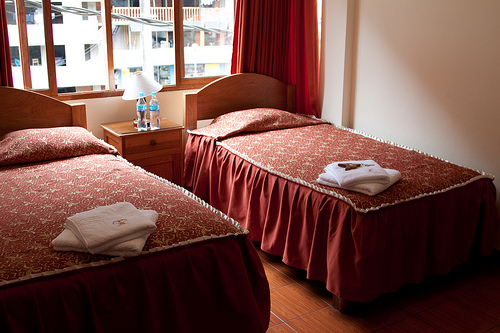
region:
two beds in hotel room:
[3, 11, 489, 316]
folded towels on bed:
[309, 152, 407, 204]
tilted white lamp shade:
[118, 67, 163, 108]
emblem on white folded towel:
[111, 215, 131, 230]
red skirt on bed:
[246, 197, 339, 267]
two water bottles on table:
[133, 88, 168, 135]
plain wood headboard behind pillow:
[176, 67, 307, 122]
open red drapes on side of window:
[231, 10, 317, 80]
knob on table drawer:
[142, 136, 167, 152]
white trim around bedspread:
[403, 188, 447, 204]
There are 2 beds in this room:
[183, 67, 499, 312]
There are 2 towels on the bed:
[50, 195, 161, 260]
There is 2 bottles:
[135, 88, 164, 135]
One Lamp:
[119, 64, 162, 127]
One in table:
[99, 119, 194, 193]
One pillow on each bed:
[191, 101, 318, 143]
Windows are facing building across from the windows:
[50, 43, 73, 73]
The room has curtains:
[226, 0, 326, 118]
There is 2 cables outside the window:
[24, 0, 231, 35]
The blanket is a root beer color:
[186, 107, 496, 303]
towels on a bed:
[310, 150, 408, 205]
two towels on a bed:
[42, 196, 172, 257]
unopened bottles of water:
[132, 82, 169, 137]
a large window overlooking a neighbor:
[0, 1, 238, 99]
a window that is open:
[0, 0, 58, 105]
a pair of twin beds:
[0, 72, 497, 332]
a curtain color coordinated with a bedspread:
[225, 4, 357, 157]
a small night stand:
[100, 111, 187, 191]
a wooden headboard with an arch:
[179, 68, 305, 133]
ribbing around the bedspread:
[192, 112, 491, 223]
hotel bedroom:
[17, 12, 454, 319]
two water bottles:
[125, 91, 175, 136]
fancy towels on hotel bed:
[297, 132, 414, 229]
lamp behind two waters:
[112, 60, 184, 145]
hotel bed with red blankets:
[171, 48, 480, 308]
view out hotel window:
[28, 12, 243, 87]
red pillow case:
[207, 70, 327, 160]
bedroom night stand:
[100, 112, 213, 211]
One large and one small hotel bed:
[0, 54, 495, 322]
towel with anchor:
[42, 188, 171, 290]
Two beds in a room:
[6, 63, 498, 332]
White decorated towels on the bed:
[298, 143, 418, 208]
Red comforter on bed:
[175, 98, 497, 321]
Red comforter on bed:
[0, 113, 282, 328]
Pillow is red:
[176, 101, 336, 144]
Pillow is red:
[0, 117, 141, 163]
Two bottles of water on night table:
[126, 86, 164, 136]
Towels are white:
[37, 194, 167, 276]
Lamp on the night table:
[106, 55, 167, 134]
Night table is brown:
[103, 123, 190, 170]